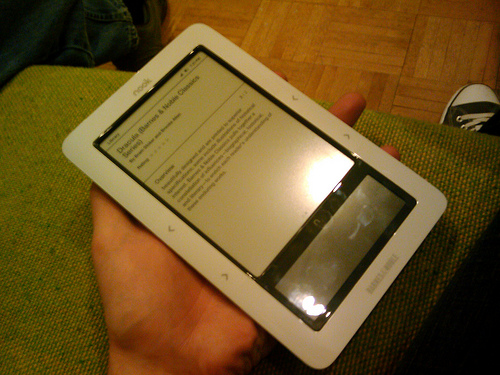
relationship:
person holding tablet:
[92, 69, 399, 374] [60, 20, 447, 372]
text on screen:
[103, 56, 273, 212] [93, 43, 418, 331]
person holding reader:
[92, 69, 399, 374] [90, 60, 458, 348]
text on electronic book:
[106, 56, 279, 216] [57, 21, 447, 371]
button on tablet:
[208, 261, 241, 292] [60, 20, 447, 372]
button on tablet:
[160, 219, 179, 234] [64, 27, 416, 366]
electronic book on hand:
[56, 18, 458, 367] [91, 88, 413, 373]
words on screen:
[124, 80, 282, 212] [93, 43, 418, 331]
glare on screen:
[291, 291, 322, 324] [115, 56, 389, 309]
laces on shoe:
[456, 110, 497, 130] [436, 81, 498, 133]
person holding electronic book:
[92, 69, 399, 374] [57, 21, 447, 371]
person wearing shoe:
[90, 83, 500, 375] [437, 79, 499, 131]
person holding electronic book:
[90, 83, 500, 375] [57, 21, 447, 371]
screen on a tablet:
[144, 125, 312, 203] [77, 41, 429, 342]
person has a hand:
[90, 83, 500, 375] [47, 183, 252, 373]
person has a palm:
[90, 83, 500, 375] [93, 221, 268, 373]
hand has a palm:
[47, 183, 252, 373] [93, 221, 268, 373]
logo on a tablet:
[364, 253, 397, 294] [60, 20, 447, 372]